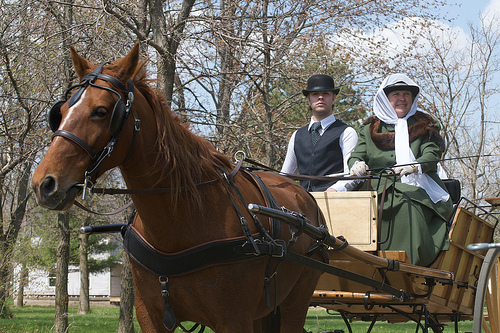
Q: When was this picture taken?
A: During day.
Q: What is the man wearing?
A: Suit.